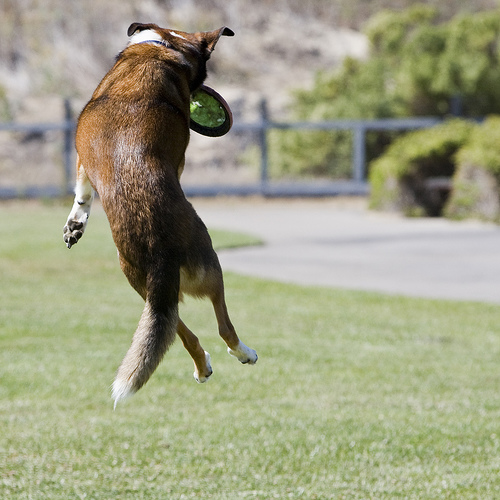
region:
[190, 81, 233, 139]
Green and black frisbee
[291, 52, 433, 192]
Small section of a tree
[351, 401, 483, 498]
Small patch of grass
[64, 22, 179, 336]
Brown and white dog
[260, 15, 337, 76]
Small section of a mountain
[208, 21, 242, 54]
The dog's right ear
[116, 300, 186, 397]
White end of the dog's tail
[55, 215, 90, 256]
The dog's left paw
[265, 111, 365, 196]
Blue fence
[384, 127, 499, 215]
Rocks that weeds on it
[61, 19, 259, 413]
Brown and white dog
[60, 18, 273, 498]
Dog jumping to catch the Frisbee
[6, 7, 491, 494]
Brown dog playing Frisbee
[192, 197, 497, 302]
Concrete driveway covering the ground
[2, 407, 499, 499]
Green and tan grass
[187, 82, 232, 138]
Small Frisbee in the dog's mouth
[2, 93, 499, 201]
Blue fence on the property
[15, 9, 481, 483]
Dog playing in the front yard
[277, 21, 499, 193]
Tree behind the blue fence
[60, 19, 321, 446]
Dog exercising in the yard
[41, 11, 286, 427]
The dog has a frisbee.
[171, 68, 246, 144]
The frisbee is green.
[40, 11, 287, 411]
The dog is airborne.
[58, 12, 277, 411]
The dog is tan and white.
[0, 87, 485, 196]
A fence is in the background.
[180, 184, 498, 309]
A walkway is near the dog.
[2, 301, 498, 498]
The grass is green.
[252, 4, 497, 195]
Trees are in the background.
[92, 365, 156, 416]
The tip of the dog's tail is white.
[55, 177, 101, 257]
The dog's paws are white.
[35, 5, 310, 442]
A dog catching a frisbee.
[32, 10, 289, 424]
A brown and white dog.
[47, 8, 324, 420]
A brown and white dog jumping in the air.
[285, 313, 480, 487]
Green grass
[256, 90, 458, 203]
A fence at the end of a road.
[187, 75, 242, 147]
A green Frisbee.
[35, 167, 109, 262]
The paw of a brown and white dog.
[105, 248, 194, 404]
The bushy tail of a dog.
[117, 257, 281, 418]
The back legs of a jumping dog.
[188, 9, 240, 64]
The brown ear of a dog.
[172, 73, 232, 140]
Frisbee in dog's mouth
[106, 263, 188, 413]
tail on back of dog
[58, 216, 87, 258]
pads on dog paw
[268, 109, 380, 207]
blue fence in the distance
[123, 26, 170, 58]
collar on white neck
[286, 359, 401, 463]
manicured green grass in park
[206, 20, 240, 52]
droopy ear on dog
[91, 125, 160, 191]
shiny coat on dog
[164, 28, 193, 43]
white patch on dog head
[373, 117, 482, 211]
bush in front of fence